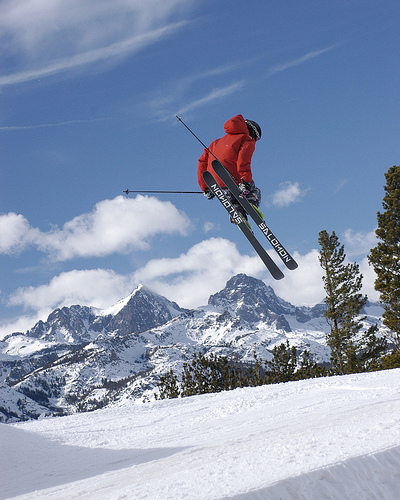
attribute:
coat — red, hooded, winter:
[181, 120, 262, 202]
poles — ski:
[116, 109, 249, 203]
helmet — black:
[242, 119, 264, 137]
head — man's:
[236, 111, 265, 145]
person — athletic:
[186, 111, 271, 225]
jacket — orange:
[184, 116, 258, 182]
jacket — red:
[177, 117, 257, 185]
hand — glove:
[237, 175, 260, 199]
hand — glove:
[248, 189, 262, 206]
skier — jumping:
[173, 111, 282, 231]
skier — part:
[195, 113, 265, 236]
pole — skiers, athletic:
[120, 188, 204, 195]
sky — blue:
[267, 89, 347, 141]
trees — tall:
[314, 157, 398, 386]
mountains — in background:
[0, 271, 395, 423]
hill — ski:
[85, 278, 277, 343]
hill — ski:
[113, 285, 190, 338]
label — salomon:
[258, 224, 290, 269]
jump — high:
[191, 90, 285, 316]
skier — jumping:
[167, 101, 287, 282]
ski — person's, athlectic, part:
[152, 96, 273, 260]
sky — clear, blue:
[211, 16, 297, 53]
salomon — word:
[251, 209, 285, 267]